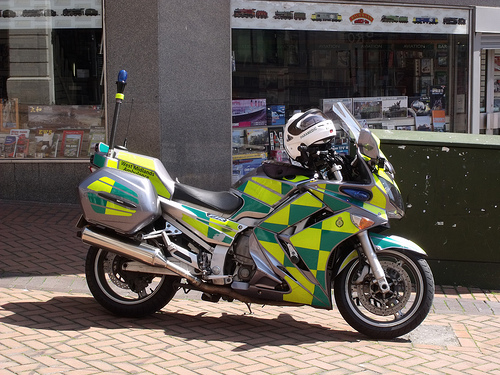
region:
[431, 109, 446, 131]
small orange box in window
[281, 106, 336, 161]
white helmet on the motorcycle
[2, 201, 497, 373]
cobblestone ground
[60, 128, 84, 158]
magazine in window with red trim on the left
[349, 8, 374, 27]
crown sign above window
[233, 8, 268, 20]
red train on window sign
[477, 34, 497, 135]
door to building in the background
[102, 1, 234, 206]
concrete pillar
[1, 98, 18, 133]
book on far left with a blond child on the cover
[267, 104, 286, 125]
blue box in the window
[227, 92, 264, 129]
a box on a display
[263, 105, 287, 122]
a box on a display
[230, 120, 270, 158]
a box on a display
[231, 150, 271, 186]
a box on a display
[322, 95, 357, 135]
a box on a display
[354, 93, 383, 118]
a box on a display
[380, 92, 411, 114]
a box on a display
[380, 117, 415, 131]
a box on a display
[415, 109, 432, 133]
a box on a display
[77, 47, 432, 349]
a motorbike parked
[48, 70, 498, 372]
MOTORCYCLE IS YELLOW AND GREEN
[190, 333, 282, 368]
a brick pavement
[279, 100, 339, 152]
a white motorcycle helmet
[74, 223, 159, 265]
exhaust pipe on a motorcycle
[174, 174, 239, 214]
a seat on a motorcycle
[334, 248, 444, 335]
a wheel on a motorcycle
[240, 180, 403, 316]
a green and yellow motorcycle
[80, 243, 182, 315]
a rear wheel on a motorcycle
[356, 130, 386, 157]
mirror on a motorcycle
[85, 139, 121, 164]
light on a motorcycle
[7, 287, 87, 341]
shadow of a motorcycle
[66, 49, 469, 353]
Police motorcycle parked on the sidewalk.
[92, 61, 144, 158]
Police light attached to the rear of the cycle.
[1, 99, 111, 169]
Magazine rack display.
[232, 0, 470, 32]
Train decorations above the store entry.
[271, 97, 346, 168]
Motorcycle helmet for rider's protection.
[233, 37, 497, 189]
Novelty store front with displays.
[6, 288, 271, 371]
brick sidewalk.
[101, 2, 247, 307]
Pillar used in construction for support.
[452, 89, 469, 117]
Store door control key box.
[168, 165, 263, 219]
Motorcycle seat for comfortable riding.